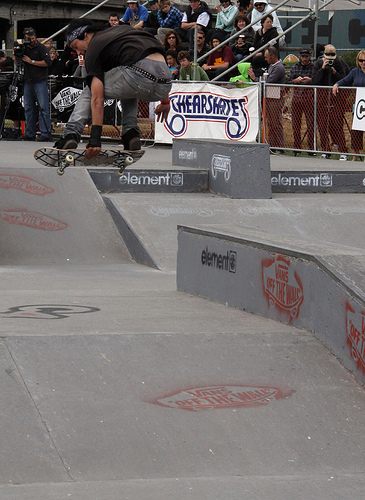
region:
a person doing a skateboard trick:
[29, 17, 178, 174]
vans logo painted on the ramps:
[145, 366, 310, 440]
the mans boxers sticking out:
[114, 46, 182, 90]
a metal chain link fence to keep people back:
[13, 58, 359, 177]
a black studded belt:
[118, 57, 184, 90]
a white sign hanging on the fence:
[151, 68, 269, 143]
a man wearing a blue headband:
[54, 14, 128, 68]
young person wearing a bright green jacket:
[223, 46, 258, 101]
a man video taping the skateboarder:
[8, 24, 66, 148]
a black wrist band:
[71, 93, 107, 165]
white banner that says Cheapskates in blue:
[149, 79, 259, 141]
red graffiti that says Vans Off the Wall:
[147, 380, 290, 410]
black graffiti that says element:
[201, 244, 237, 273]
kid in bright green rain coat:
[229, 61, 254, 89]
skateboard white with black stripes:
[33, 147, 144, 172]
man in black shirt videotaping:
[13, 26, 54, 140]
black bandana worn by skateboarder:
[66, 24, 94, 43]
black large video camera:
[13, 36, 29, 61]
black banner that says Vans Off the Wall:
[52, 77, 123, 124]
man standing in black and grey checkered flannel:
[288, 47, 318, 154]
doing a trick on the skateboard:
[38, 21, 199, 180]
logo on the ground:
[166, 379, 318, 422]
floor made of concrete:
[44, 299, 350, 478]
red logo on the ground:
[143, 381, 314, 423]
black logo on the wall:
[194, 240, 246, 277]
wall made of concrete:
[179, 223, 346, 314]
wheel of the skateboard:
[53, 149, 81, 166]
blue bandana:
[60, 28, 93, 43]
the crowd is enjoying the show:
[134, 1, 312, 67]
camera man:
[14, 25, 62, 94]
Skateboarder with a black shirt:
[31, 19, 220, 184]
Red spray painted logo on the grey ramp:
[121, 372, 278, 439]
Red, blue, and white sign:
[134, 79, 271, 152]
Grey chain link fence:
[10, 55, 358, 158]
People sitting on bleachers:
[20, 7, 312, 136]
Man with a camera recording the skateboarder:
[3, 27, 62, 142]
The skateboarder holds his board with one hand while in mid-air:
[34, 23, 184, 182]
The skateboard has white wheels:
[20, 138, 156, 172]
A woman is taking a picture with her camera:
[307, 44, 358, 143]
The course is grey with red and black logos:
[13, 140, 355, 478]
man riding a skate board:
[20, 18, 212, 191]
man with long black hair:
[35, 17, 163, 181]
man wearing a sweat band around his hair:
[23, 20, 190, 176]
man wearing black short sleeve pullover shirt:
[26, 24, 188, 179]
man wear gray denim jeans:
[22, 21, 188, 184]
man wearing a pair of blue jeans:
[15, 21, 61, 159]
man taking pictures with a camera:
[10, 20, 69, 141]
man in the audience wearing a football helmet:
[296, 31, 349, 129]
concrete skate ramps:
[19, 164, 308, 463]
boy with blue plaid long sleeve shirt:
[143, 0, 187, 28]